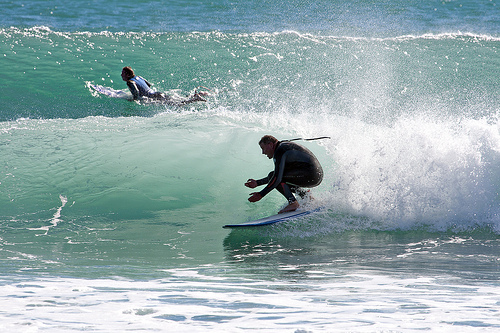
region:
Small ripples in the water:
[22, 271, 97, 331]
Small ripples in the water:
[106, 275, 156, 322]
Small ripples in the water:
[192, 286, 287, 326]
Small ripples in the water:
[317, 277, 382, 327]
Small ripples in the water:
[408, 279, 464, 330]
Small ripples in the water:
[30, 182, 85, 225]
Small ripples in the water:
[95, 170, 159, 252]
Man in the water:
[202, 110, 331, 273]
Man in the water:
[111, 54, 238, 126]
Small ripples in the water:
[410, 40, 447, 153]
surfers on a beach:
[20, 11, 470, 285]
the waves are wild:
[21, 8, 494, 278]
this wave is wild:
[34, 80, 498, 235]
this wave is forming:
[9, 1, 478, 83]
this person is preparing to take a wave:
[98, 51, 224, 115]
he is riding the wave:
[202, 129, 382, 236]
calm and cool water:
[29, 239, 484, 318]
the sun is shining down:
[23, 7, 473, 259]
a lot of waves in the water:
[19, 11, 498, 175]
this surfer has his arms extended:
[219, 137, 282, 222]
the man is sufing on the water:
[226, 133, 328, 233]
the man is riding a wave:
[226, 134, 328, 233]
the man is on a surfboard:
[226, 131, 332, 228]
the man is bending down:
[243, 127, 329, 212]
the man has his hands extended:
[243, 171, 273, 205]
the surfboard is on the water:
[224, 204, 327, 231]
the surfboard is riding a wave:
[222, 205, 317, 231]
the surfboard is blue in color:
[223, 202, 328, 224]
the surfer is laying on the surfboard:
[87, 63, 217, 109]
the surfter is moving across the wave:
[87, 66, 217, 106]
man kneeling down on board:
[244, 80, 337, 232]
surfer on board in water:
[92, 39, 211, 121]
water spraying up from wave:
[363, 72, 449, 123]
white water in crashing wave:
[338, 138, 461, 230]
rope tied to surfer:
[282, 128, 379, 163]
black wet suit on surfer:
[277, 135, 343, 200]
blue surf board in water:
[202, 190, 337, 242]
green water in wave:
[108, 180, 180, 225]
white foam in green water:
[253, 257, 350, 330]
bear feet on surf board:
[265, 174, 330, 232]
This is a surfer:
[188, 112, 354, 204]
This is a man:
[210, 109, 346, 279]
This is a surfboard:
[218, 188, 300, 253]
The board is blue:
[205, 157, 335, 297]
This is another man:
[93, 45, 223, 130]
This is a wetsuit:
[250, 93, 302, 199]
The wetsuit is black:
[183, 74, 373, 224]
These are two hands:
[239, 169, 253, 209]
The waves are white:
[315, 121, 427, 203]